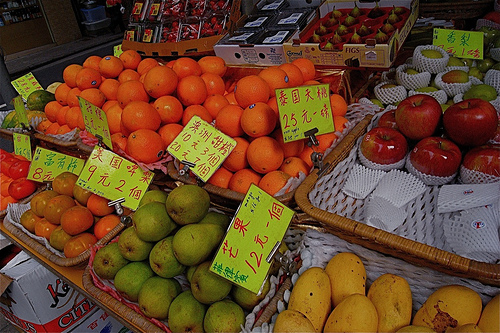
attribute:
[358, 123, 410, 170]
apple — red, wrapped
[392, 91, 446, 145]
apple — red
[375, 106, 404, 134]
apple — red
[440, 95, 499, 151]
apple — red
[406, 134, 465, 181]
apple — red, wrapped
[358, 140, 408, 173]
casing — white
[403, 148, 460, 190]
casing — white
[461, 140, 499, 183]
apple — wrapped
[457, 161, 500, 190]
casing — white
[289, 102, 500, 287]
basket — wicker